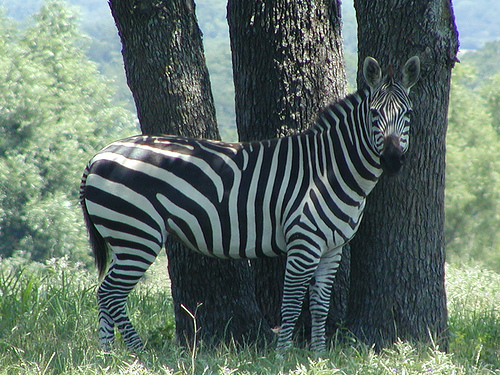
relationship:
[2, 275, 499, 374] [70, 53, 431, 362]
grass underneath zebra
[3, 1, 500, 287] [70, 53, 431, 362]
trees behind zebra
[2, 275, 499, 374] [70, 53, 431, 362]
grass below zebra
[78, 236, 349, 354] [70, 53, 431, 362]
legs on zebra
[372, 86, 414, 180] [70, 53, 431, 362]
face on zebra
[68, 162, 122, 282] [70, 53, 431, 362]
tail on zebra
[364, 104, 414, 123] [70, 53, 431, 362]
eyes on zebra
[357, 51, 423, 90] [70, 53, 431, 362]
ears on zebra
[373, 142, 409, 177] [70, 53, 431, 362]
nose on zebra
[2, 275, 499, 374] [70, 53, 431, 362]
grass under zebra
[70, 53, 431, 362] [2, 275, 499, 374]
zebra standing in grass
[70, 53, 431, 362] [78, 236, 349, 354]
zebra has legs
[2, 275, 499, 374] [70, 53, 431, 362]
grass behind zebra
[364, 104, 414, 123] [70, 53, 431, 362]
eyes are on zebra